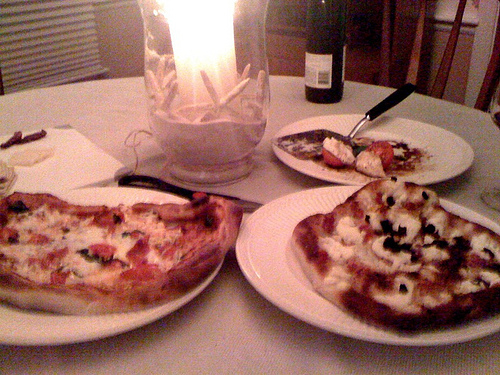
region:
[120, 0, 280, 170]
A candle in a vase.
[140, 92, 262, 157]
The vase is full of sand.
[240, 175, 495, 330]
A small pizza on a plate.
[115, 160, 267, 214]
A pair of kitchen scissors.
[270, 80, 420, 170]
A spatula with food residue on it.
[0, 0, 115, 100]
Blinds covering a window.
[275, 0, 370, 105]
A dark glass bottle.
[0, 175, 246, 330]
The pizza has been cut.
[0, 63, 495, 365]
The table is covered with a table cloth.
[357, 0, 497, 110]
The back of a chair.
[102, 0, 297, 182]
hurricane vase with starvish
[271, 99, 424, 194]
silver and black spatula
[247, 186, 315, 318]
ceramic designed round plate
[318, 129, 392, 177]
shells with with pastry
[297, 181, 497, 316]
oblong shaped pizza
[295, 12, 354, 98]
brown wine bottle on table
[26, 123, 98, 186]
white palte with appetizers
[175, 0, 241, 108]
candle lit in hurrican vase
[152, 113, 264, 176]
sand inside hurricane vase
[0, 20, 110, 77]
white horizontal blinds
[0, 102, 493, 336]
food on white plates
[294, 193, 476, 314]
slice of pizza on plate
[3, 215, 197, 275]
slice of pizza on plate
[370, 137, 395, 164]
red tomato on plate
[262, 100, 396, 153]
spatula on white plate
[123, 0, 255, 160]
crystal candle holder on table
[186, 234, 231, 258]
crust of pizza on plate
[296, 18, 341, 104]
bottle of wine on table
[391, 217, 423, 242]
feta cheese on pizza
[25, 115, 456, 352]
Three plate are in table.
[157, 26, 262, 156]
Candle is on.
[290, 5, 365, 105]
Bottle is in the table.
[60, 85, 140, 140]
Table cloth is white color.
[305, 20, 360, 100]
Bottle is brown color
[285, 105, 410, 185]
Silverware is in plate.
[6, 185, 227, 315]
pizza is in plate.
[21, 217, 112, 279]
cheese is white color.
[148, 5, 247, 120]
Candle is white color.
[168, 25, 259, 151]
candle is in jar.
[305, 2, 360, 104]
black glass bottle sitting on table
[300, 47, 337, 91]
white sticker on back of bottle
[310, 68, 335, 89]
barcode on back of bottle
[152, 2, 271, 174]
candle with clear glass cover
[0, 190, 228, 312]
cooked pizza on white plate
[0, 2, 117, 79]
white window blinds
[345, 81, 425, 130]
black handle of spatula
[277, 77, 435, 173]
spatula laying on white plate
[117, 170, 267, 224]
pair of scissors sitting on table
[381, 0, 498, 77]
brown wooden chair back